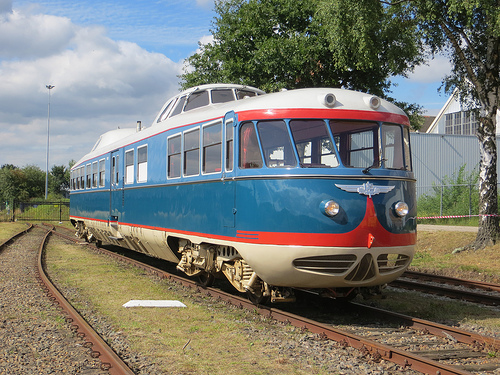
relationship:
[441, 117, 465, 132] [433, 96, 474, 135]
windows attached to house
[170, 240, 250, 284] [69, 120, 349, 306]
wheels attached to train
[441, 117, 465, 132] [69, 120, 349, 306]
windows are on train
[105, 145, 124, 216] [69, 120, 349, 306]
door attached to train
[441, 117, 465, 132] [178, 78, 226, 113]
windows are on roof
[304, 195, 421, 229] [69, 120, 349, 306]
headlights attached to train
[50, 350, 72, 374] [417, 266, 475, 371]
rocks on top of tracks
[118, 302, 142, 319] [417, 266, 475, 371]
grass in tracks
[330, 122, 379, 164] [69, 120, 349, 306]
windshield attached to train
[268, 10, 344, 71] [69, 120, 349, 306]
tree by train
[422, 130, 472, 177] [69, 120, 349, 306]
fence next to train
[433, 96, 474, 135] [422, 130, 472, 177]
house behind fence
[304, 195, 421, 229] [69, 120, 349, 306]
headlights are on train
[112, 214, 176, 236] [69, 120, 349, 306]
stripe along train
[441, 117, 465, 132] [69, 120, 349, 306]
windows are alongside train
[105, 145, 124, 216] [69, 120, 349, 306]
door on train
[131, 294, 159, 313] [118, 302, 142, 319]
object in grass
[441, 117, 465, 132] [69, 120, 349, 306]
windows are on top of train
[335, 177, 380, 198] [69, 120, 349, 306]
emblem on train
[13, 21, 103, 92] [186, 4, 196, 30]
clouds are in sky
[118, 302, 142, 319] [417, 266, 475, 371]
grass between tracks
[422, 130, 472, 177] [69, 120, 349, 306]
fence behind train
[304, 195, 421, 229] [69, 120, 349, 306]
headlights are in front of train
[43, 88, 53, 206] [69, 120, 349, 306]
pole behind train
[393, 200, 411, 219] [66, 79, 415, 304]
headlights on train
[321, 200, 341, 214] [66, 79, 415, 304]
headlights on train